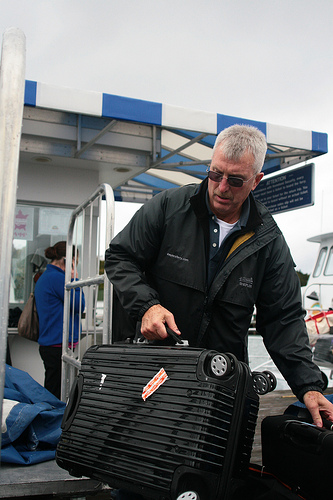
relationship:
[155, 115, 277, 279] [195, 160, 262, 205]
man has sunglasses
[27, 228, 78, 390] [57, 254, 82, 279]
woman has phone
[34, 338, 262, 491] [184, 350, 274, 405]
suitcase has wheels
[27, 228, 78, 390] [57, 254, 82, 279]
woman on phone